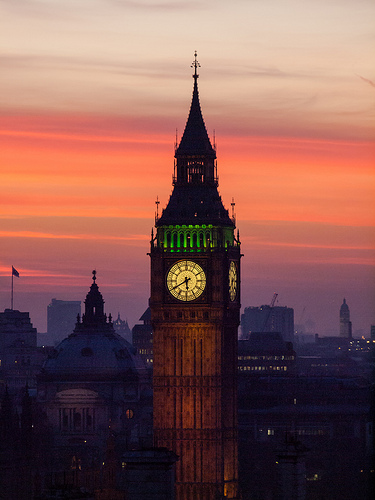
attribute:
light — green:
[146, 223, 220, 245]